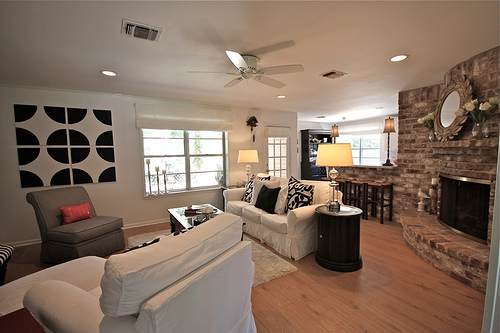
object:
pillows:
[250, 180, 281, 206]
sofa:
[227, 161, 357, 265]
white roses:
[455, 97, 500, 123]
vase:
[471, 123, 490, 139]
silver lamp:
[234, 145, 264, 180]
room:
[7, 12, 499, 326]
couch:
[223, 172, 343, 262]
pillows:
[242, 175, 270, 203]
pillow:
[59, 202, 93, 225]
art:
[13, 104, 117, 189]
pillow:
[284, 176, 315, 214]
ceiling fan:
[187, 50, 304, 88]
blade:
[225, 50, 248, 72]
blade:
[263, 64, 305, 75]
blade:
[253, 75, 286, 89]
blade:
[224, 77, 245, 90]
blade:
[185, 69, 228, 73]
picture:
[13, 104, 117, 189]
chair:
[26, 185, 125, 263]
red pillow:
[59, 202, 93, 225]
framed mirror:
[432, 70, 473, 142]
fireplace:
[437, 173, 489, 243]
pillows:
[273, 180, 288, 215]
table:
[166, 198, 241, 237]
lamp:
[316, 143, 354, 212]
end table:
[315, 205, 364, 272]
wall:
[297, 114, 399, 222]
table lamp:
[380, 116, 397, 166]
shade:
[382, 113, 398, 133]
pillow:
[254, 185, 281, 213]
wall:
[0, 87, 146, 248]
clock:
[246, 116, 259, 133]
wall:
[227, 108, 267, 187]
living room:
[0, 0, 500, 333]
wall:
[397, 43, 499, 293]